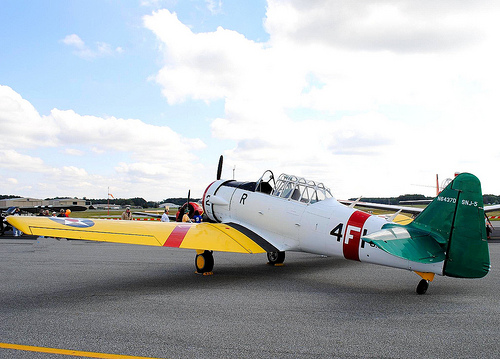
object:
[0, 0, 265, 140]
blue sky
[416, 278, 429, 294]
tire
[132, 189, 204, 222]
airplane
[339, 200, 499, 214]
airplane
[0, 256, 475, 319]
shadow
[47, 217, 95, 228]
circle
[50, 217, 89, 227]
star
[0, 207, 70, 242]
people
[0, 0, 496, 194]
cloud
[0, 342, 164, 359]
line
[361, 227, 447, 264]
wings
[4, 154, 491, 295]
airplane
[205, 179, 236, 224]
motor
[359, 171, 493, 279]
green tail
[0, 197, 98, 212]
buildings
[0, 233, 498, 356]
ground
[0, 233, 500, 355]
runway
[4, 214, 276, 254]
wing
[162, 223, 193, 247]
stripe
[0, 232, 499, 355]
tarmac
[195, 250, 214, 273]
tire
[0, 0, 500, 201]
sky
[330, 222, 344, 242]
number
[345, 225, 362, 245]
letter